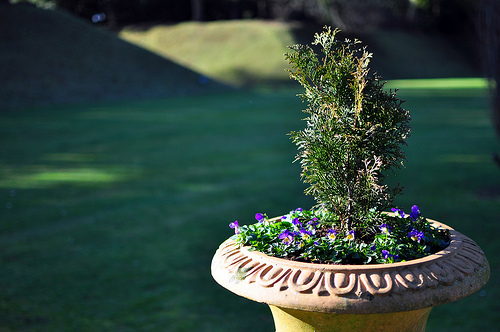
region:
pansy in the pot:
[278, 228, 296, 243]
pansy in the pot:
[327, 229, 338, 242]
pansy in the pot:
[406, 205, 421, 221]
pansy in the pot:
[343, 230, 362, 247]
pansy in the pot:
[379, 250, 394, 263]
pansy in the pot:
[253, 215, 264, 223]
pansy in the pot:
[347, 230, 357, 238]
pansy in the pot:
[380, 246, 394, 255]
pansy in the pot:
[230, 219, 243, 236]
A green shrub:
[290, 30, 409, 230]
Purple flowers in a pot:
[226, 208, 446, 260]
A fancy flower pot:
[215, 205, 486, 330]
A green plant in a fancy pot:
[210, 27, 490, 329]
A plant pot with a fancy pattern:
[210, 202, 492, 329]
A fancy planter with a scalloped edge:
[210, 202, 495, 329]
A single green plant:
[283, 31, 410, 228]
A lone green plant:
[287, 25, 405, 224]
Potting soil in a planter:
[263, 211, 424, 256]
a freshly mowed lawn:
[0, 79, 499, 328]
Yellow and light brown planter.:
[209, 205, 490, 330]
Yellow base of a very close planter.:
[261, 300, 434, 328]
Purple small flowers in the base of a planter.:
[226, 204, 437, 263]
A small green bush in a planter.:
[281, 25, 411, 231]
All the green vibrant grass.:
[8, 73, 499, 330]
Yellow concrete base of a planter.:
[269, 303, 432, 329]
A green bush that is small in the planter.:
[278, 25, 413, 232]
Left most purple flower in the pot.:
[228, 218, 244, 234]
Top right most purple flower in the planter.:
[408, 205, 421, 220]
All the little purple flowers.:
[231, 203, 450, 265]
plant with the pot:
[283, 25, 419, 278]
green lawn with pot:
[67, 98, 476, 313]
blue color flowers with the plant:
[251, 212, 419, 262]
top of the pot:
[227, 218, 497, 300]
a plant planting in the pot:
[289, 31, 396, 305]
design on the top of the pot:
[228, 256, 460, 306]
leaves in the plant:
[316, 144, 359, 218]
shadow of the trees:
[108, 95, 181, 300]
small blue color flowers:
[270, 230, 384, 266]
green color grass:
[437, 79, 486, 197]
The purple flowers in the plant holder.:
[232, 196, 441, 263]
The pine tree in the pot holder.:
[286, 33, 404, 227]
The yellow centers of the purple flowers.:
[287, 225, 353, 245]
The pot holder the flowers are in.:
[202, 224, 498, 330]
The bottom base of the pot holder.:
[269, 303, 434, 330]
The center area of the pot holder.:
[261, 210, 442, 264]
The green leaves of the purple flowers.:
[241, 212, 427, 258]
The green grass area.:
[5, 93, 498, 330]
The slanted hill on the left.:
[17, 3, 212, 115]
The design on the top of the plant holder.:
[225, 228, 474, 295]